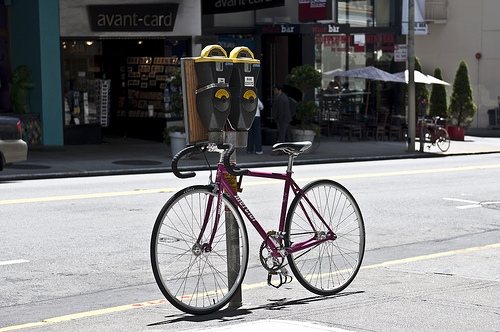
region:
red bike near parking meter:
[167, 45, 329, 326]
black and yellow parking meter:
[171, 10, 288, 165]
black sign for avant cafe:
[27, 0, 227, 40]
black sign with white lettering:
[51, 7, 218, 47]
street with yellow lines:
[17, 147, 494, 329]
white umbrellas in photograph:
[334, 41, 461, 119]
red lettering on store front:
[305, 22, 430, 72]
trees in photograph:
[385, 55, 497, 202]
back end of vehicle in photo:
[0, 88, 42, 210]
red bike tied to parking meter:
[147, 45, 411, 302]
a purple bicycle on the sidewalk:
[138, 136, 380, 319]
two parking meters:
[177, 38, 277, 313]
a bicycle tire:
[278, 172, 388, 299]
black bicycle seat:
[259, 132, 317, 175]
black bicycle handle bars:
[165, 140, 247, 192]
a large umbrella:
[333, 61, 413, 87]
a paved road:
[360, 155, 498, 262]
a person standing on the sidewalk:
[264, 80, 298, 147]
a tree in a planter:
[447, 58, 482, 144]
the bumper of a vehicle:
[0, 112, 35, 175]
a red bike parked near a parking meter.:
[135, 118, 413, 329]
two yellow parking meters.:
[169, 33, 283, 314]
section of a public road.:
[360, 193, 435, 240]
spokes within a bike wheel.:
[293, 214, 355, 268]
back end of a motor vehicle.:
[0, 100, 27, 171]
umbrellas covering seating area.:
[315, 56, 468, 86]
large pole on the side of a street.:
[386, 0, 426, 215]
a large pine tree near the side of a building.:
[445, 41, 488, 176]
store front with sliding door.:
[62, 33, 190, 154]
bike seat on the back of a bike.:
[261, 126, 338, 160]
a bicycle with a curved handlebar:
[154, 132, 259, 187]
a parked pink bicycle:
[151, 136, 376, 306]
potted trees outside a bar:
[426, 68, 481, 139]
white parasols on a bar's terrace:
[341, 53, 437, 116]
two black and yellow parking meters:
[188, 37, 263, 145]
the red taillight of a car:
[11, 118, 31, 145]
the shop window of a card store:
[61, 5, 195, 144]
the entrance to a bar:
[276, 23, 320, 130]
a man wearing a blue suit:
[271, 81, 299, 151]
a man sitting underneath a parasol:
[325, 62, 365, 114]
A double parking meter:
[177, 43, 280, 161]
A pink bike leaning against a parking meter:
[150, 135, 403, 312]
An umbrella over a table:
[339, 52, 404, 139]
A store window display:
[65, 37, 119, 145]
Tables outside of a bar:
[332, 75, 454, 143]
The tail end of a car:
[1, 102, 37, 163]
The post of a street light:
[392, 10, 433, 160]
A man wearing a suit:
[264, 76, 308, 150]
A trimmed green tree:
[449, 52, 479, 128]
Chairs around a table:
[333, 106, 388, 137]